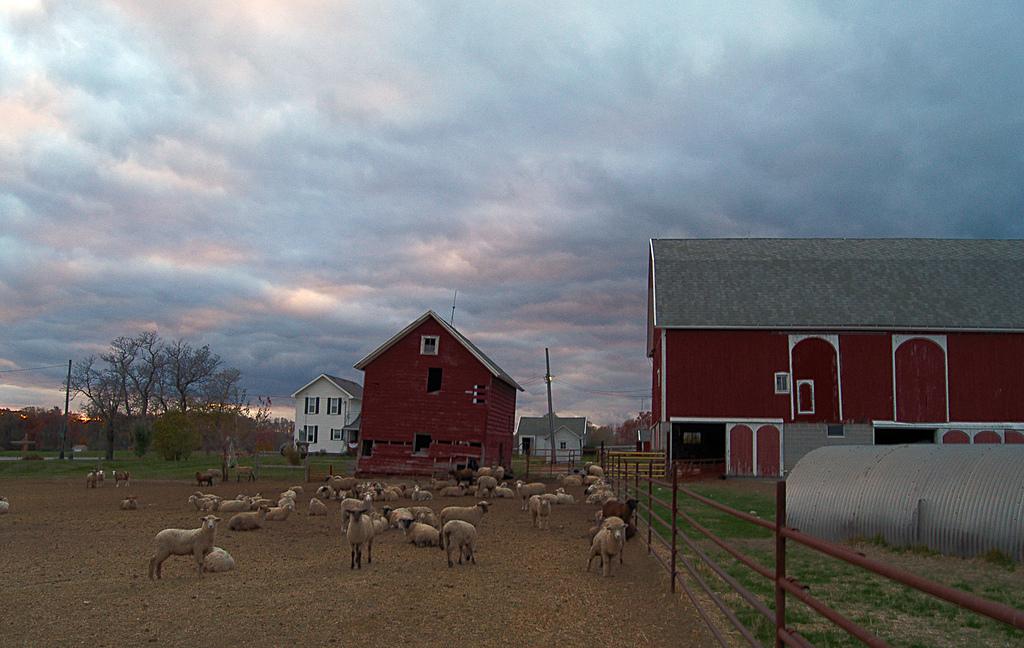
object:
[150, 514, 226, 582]
sheep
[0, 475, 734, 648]
grass field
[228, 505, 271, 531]
sheep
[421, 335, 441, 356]
window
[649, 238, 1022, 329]
roof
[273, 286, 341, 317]
portion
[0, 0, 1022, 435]
sky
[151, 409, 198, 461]
tree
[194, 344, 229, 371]
leaves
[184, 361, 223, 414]
branches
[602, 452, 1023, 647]
fence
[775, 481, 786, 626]
poles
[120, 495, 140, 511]
sheep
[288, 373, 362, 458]
building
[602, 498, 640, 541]
sheep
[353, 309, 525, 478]
building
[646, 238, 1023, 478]
barn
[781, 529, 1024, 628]
pipe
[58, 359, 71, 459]
wires